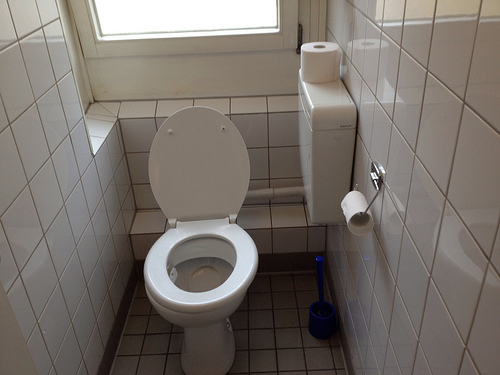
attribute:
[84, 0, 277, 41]
window — closed, glass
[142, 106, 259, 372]
toilet — white, porcelain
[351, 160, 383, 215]
holder — silver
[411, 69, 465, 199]
tile — white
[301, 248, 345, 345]
toilet brush — blue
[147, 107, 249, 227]
seat cover — toilet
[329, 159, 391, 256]
toilet paper — roll